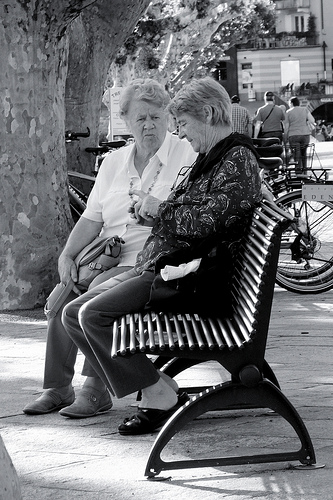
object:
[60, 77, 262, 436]
women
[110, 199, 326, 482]
bench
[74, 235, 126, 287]
purse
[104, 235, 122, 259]
lap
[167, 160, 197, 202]
glasses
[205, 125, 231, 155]
neck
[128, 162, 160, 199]
necklace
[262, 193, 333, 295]
wheel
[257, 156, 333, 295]
bike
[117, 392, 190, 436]
shoe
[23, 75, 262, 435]
2nd woman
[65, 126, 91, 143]
handlebars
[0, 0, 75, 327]
tree trunk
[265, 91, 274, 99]
hat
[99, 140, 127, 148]
seat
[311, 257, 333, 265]
bike rack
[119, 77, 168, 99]
gray hair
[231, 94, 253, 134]
people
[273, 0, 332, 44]
building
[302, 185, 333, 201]
sign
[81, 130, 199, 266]
white shirt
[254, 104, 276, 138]
shoulder bag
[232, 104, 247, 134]
plaid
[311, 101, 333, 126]
dark entrance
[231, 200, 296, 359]
back